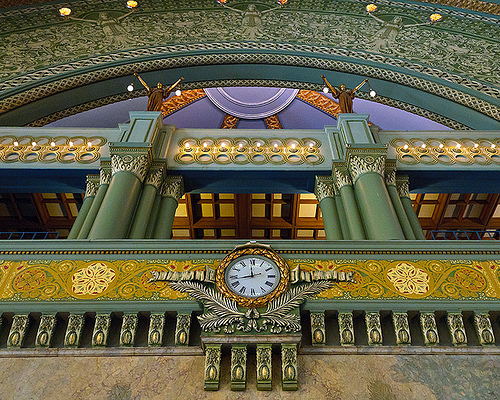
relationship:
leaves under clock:
[212, 297, 292, 329] [210, 242, 292, 305]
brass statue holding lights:
[120, 56, 197, 149] [317, 63, 389, 99]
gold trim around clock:
[269, 254, 294, 296] [211, 237, 296, 313]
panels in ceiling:
[178, 193, 325, 233] [26, 185, 493, 221]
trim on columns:
[61, 130, 421, 216] [66, 142, 185, 237]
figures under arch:
[164, 143, 320, 189] [154, 33, 423, 204]